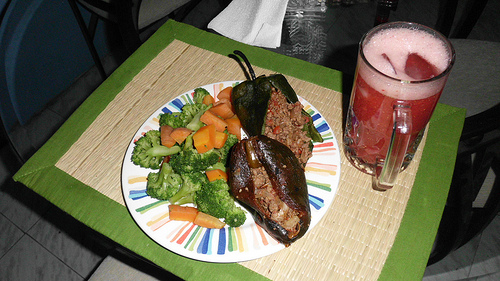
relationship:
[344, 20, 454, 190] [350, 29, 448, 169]
mug has drink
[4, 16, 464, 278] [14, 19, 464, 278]
placemat bounded by border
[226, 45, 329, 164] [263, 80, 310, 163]
stuffed pepper stuffed rice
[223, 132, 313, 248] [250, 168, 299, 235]
stuffed pepper stuffed rice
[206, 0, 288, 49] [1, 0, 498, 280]
napkin on table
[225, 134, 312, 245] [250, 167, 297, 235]
pepper filled with meat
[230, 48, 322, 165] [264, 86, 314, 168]
pepper filled with meat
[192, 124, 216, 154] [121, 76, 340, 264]
carrot on plate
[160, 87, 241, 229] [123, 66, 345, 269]
carrot on plate